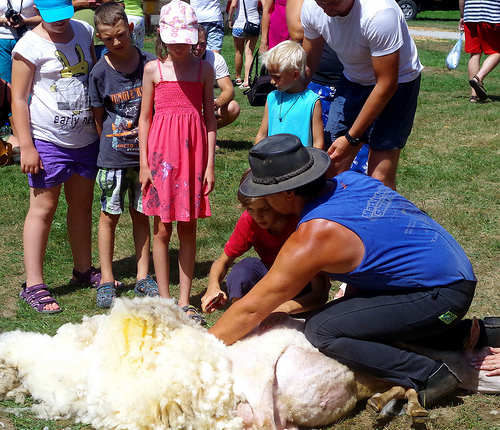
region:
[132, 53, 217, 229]
a dark pink dress on a girl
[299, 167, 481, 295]
a blue shirt on a man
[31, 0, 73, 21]
a blue cap on a girl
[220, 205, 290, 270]
a red shirt on a boy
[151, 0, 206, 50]
a pink cap on a girl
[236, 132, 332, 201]
a black hat on a man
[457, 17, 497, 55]
red shorts on a person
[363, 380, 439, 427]
the hooves of a sheep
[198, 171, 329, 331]
a boy shearing a sheep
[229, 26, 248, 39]
blue shorts on a woman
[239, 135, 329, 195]
The hat the man is wearing.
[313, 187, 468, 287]
The blue tank top the man is wearing.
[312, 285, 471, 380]
The pants the man is wearing.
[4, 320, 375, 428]
The sheep on the ground.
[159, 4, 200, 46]
The pink hat the girl is wearing.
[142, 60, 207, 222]
The pink dress the girl is wearing.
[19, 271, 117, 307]
The purple sandals the girl is wearing.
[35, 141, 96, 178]
The purple shorts the girl is wearing.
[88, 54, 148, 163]
The dark blue shirt the boy is wearing.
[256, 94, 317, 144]
The light blue shirt the boy is wearing.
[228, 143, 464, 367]
this is a man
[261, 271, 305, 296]
the man is light skinned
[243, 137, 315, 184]
this is a hat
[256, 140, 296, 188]
the hat is black in color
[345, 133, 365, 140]
this is a wrist watch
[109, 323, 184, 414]
this is a wool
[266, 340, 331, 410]
this is a sheep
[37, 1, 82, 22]
this is a cap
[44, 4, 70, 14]
the cap is blue in color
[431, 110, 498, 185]
this is a grass area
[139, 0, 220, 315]
A girl in a bright pink dress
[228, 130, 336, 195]
A black hat on a man's head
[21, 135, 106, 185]
Purple shorts on a woman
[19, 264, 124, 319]
Purple sandals on a woman's feet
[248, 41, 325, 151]
A boy in a light blue shirt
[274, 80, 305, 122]
A necklace hanging around the boy's neck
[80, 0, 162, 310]
A boy wearing a dark shirt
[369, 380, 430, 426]
Hooves sticking out from under the man's leg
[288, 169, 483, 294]
A blue tank top on the man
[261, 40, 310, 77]
The boy's light blonde hair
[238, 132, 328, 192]
The hat is black.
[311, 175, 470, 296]
His shirt is blue.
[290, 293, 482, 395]
His pants are black.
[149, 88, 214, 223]
Her shirt is pink.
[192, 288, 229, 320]
The boy is holding scissors.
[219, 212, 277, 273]
He has a red shirt.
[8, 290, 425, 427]
The sheep is on the ground.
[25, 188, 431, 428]
They are cutting the hair off the sheep.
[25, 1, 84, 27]
She is wearing a blue hat.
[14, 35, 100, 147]
She is wearing a white shirt.